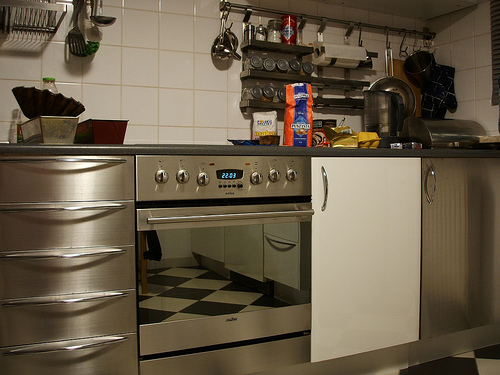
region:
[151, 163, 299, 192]
Knobs on the stove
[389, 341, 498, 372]
Tiles on the floor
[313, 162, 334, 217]
Handle of a cabinet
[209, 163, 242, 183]
Time on the stove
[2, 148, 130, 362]
Five handles on drawers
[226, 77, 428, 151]
Items on the countertop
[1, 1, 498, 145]
White tiles on the walls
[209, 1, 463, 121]
Hanging kitchen appliances against wall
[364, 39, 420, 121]
A hanging frying pan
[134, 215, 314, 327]
Reflections on the oven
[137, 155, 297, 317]
An oven in the photo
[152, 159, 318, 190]
Knobs on the oven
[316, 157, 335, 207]
A handle in the photo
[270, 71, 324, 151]
A packet on the shelf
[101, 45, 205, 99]
Tiled wall in the room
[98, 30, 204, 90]
A wall in the kitchen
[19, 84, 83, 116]
A bowl in the kitchen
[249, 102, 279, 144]
A packet of floor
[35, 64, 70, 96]
A bottle in the kitchen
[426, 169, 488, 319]
A cabinet door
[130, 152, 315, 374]
front of stainless steel oven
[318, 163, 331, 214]
shiny stainless steel kitchen cabinet handle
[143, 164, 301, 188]
six metal oven knobs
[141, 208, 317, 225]
one long stainless steel oven handle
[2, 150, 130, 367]
several stainless steel kitchen cabinet handles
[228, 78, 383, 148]
several products on kitchen counter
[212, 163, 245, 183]
oven panel clock readout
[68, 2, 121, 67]
several kitchen utensils hanging in kitchen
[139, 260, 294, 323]
black and white checkered kitchen tile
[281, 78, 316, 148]
blue and red food bag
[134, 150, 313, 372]
A shiny steel kitchen oven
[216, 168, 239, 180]
Blue digital numbers on the oven's front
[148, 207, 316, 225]
A long silver oven door handle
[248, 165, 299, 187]
Knobs on the oven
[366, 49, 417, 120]
A steel pan hanging on a rack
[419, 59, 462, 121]
A dark oven mitt hanging on a rack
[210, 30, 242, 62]
A small silver funnel hanging on a rack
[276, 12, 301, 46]
A red canister on a shelf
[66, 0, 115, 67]
Kitchen utensils hanging on a rack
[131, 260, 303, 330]
The reflection of the patterned floor in the oven door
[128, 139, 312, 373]
an oven in the kitchen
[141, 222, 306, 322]
a reflection in the oven door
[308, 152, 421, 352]
a white cabinet by the stove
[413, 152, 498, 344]
a silver cupboard by the white one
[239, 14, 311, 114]
a spice rack on the wall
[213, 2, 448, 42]
a rail on the wall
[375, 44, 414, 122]
a pan on a hook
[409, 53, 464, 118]
a mitt on a hook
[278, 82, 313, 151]
a bag on the counter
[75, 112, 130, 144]
a pan on the counter